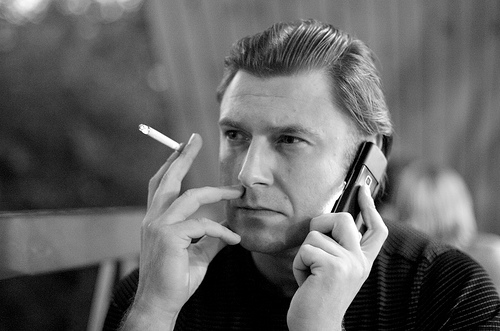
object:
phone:
[330, 140, 388, 247]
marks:
[282, 23, 349, 72]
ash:
[137, 123, 149, 134]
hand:
[119, 131, 245, 330]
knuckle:
[330, 211, 355, 233]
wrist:
[120, 293, 183, 331]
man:
[118, 15, 500, 331]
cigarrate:
[137, 123, 181, 151]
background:
[0, 3, 499, 234]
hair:
[216, 17, 395, 137]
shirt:
[108, 219, 500, 331]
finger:
[298, 182, 388, 251]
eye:
[219, 125, 309, 144]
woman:
[391, 157, 481, 250]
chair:
[0, 253, 126, 331]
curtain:
[143, 0, 497, 223]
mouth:
[227, 202, 288, 221]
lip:
[232, 203, 287, 220]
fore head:
[224, 73, 323, 118]